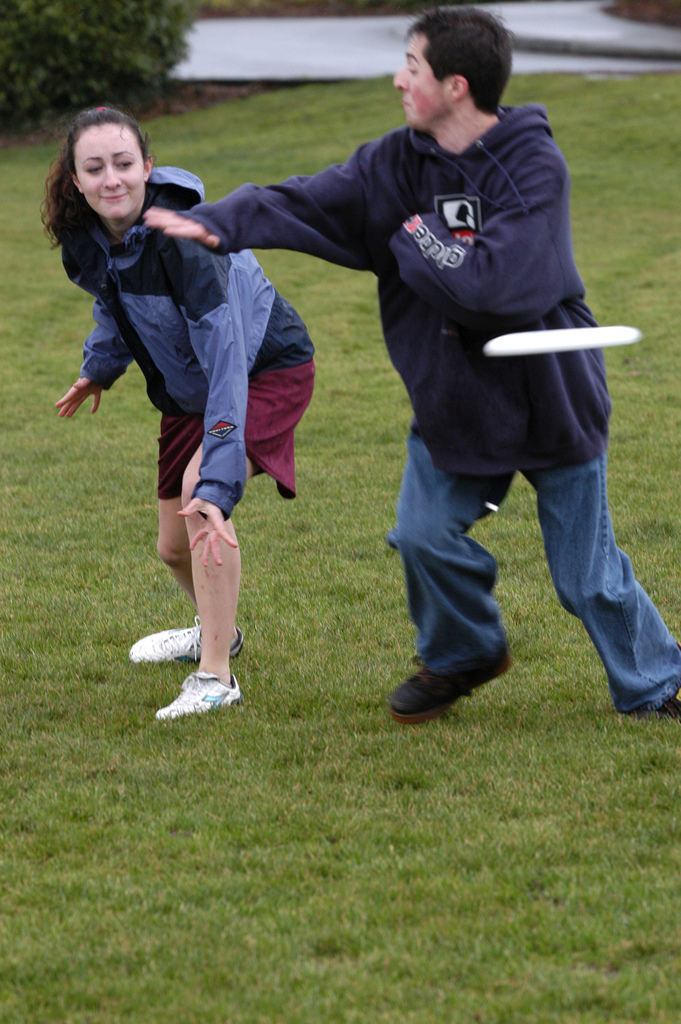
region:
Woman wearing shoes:
[117, 609, 267, 726]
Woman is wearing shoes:
[113, 598, 255, 728]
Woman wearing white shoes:
[120, 611, 270, 727]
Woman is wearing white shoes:
[114, 606, 256, 726]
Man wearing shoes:
[382, 631, 679, 740]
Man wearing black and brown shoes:
[385, 627, 676, 736]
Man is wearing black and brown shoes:
[379, 619, 679, 736]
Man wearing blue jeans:
[382, 398, 679, 720]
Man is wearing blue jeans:
[376, 394, 679, 723]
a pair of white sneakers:
[126, 607, 245, 726]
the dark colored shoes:
[381, 641, 672, 734]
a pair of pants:
[384, 418, 676, 717]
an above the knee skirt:
[150, 348, 325, 496]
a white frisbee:
[481, 316, 645, 365]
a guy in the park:
[145, 8, 679, 724]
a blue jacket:
[61, 161, 311, 517]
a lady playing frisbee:
[36, 98, 313, 724]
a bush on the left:
[0, 0, 216, 129]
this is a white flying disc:
[465, 274, 660, 379]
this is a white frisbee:
[409, 283, 653, 394]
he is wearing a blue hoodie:
[145, 0, 679, 779]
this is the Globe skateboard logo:
[425, 181, 497, 260]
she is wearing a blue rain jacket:
[12, 68, 355, 564]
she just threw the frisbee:
[33, 73, 672, 749]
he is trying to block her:
[12, 0, 677, 727]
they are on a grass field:
[7, 12, 679, 741]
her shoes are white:
[93, 602, 305, 738]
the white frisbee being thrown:
[486, 315, 640, 365]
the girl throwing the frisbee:
[23, 91, 307, 737]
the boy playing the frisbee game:
[166, 13, 675, 735]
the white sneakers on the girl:
[111, 612, 282, 730]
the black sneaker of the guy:
[383, 622, 555, 747]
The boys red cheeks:
[408, 72, 448, 119]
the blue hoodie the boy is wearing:
[191, 118, 642, 478]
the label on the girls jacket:
[206, 403, 252, 445]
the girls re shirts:
[123, 358, 340, 500]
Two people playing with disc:
[43, 10, 676, 980]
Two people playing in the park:
[43, 14, 679, 742]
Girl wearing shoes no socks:
[7, 96, 339, 960]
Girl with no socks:
[29, 43, 310, 744]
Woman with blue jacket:
[0, 82, 341, 756]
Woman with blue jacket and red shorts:
[17, 89, 306, 739]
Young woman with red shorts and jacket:
[11, 62, 320, 742]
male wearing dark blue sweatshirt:
[132, 4, 671, 769]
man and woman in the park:
[36, 6, 680, 716]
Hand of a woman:
[169, 492, 240, 576]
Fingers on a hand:
[181, 529, 242, 570]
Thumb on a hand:
[170, 501, 202, 520]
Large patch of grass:
[234, 799, 410, 918]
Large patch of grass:
[31, 891, 275, 1011]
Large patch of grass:
[335, 822, 542, 984]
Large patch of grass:
[31, 766, 266, 899]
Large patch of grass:
[192, 846, 407, 1020]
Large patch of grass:
[423, 804, 653, 991]